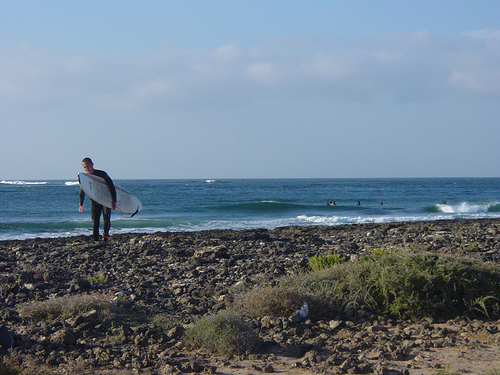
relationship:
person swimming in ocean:
[354, 200, 361, 207] [1, 177, 500, 244]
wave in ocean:
[433, 202, 489, 215] [1, 177, 500, 244]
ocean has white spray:
[1, 177, 500, 244] [435, 201, 489, 217]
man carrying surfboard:
[75, 151, 119, 240] [75, 170, 144, 214]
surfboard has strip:
[75, 170, 144, 214] [79, 171, 137, 195]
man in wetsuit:
[75, 151, 119, 240] [76, 170, 117, 239]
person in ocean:
[354, 200, 361, 207] [1, 177, 500, 244]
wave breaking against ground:
[433, 202, 489, 215] [1, 217, 498, 375]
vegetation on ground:
[235, 248, 500, 317] [1, 217, 498, 375]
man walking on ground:
[75, 151, 119, 240] [1, 217, 498, 375]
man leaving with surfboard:
[75, 151, 119, 240] [75, 170, 144, 214]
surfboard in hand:
[75, 170, 144, 214] [110, 199, 118, 209]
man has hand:
[75, 151, 119, 240] [110, 199, 118, 209]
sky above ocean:
[1, 2, 499, 181] [1, 177, 500, 244]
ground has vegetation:
[1, 217, 498, 375] [235, 248, 500, 317]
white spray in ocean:
[435, 201, 489, 217] [1, 177, 500, 244]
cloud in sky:
[285, 33, 499, 119] [1, 2, 499, 181]